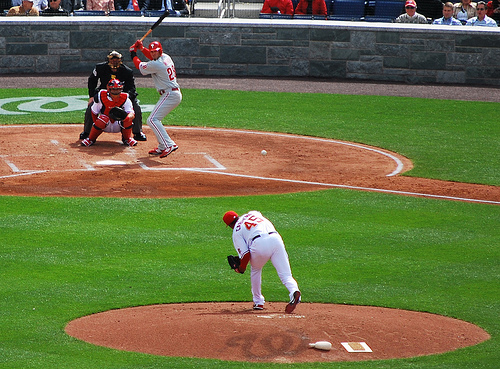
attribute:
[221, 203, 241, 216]
hat — red 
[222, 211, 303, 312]
pitcher — pitching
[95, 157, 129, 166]
plate — white, home